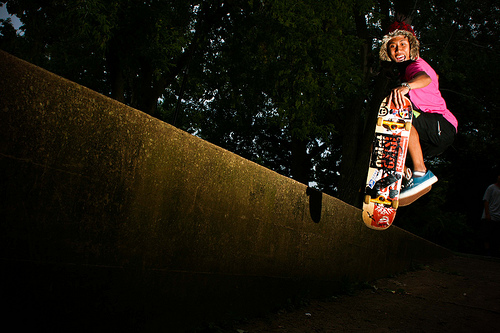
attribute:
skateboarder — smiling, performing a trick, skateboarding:
[377, 22, 459, 208]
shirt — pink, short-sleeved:
[404, 57, 458, 134]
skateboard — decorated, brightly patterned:
[362, 93, 413, 230]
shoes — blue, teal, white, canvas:
[397, 169, 438, 208]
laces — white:
[403, 167, 413, 181]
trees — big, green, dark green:
[0, 1, 497, 241]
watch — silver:
[400, 81, 411, 92]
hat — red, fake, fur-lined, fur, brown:
[380, 21, 420, 63]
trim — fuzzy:
[380, 30, 420, 63]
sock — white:
[413, 170, 427, 178]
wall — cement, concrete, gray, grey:
[0, 48, 453, 333]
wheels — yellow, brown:
[364, 117, 412, 210]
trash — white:
[304, 311, 312, 317]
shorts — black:
[412, 113, 457, 159]